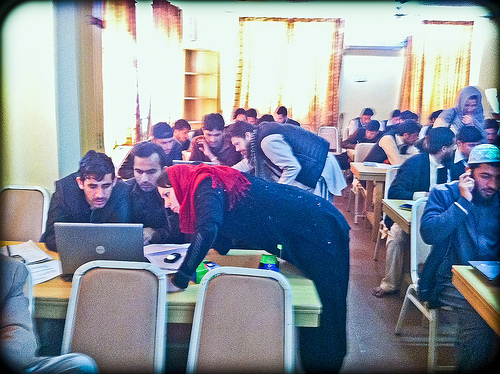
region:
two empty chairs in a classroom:
[56, 255, 298, 372]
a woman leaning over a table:
[146, 160, 358, 372]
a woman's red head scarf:
[162, 161, 252, 236]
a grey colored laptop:
[53, 217, 149, 279]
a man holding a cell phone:
[418, 144, 499, 371]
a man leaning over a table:
[221, 117, 348, 209]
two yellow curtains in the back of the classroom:
[233, 16, 473, 146]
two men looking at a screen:
[42, 137, 185, 248]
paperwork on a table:
[0, 235, 65, 286]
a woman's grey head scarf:
[455, 86, 487, 132]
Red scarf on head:
[158, 163, 239, 221]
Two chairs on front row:
[59, 262, 287, 372]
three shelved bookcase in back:
[173, 45, 233, 119]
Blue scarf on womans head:
[437, 84, 490, 119]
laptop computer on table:
[45, 217, 160, 257]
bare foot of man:
[364, 270, 403, 299]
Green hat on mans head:
[468, 144, 498, 164]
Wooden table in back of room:
[348, 158, 389, 248]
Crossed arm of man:
[2, 253, 47, 373]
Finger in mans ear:
[452, 167, 482, 206]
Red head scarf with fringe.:
[154, 153, 251, 245]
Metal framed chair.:
[185, 258, 305, 372]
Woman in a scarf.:
[144, 153, 360, 373]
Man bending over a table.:
[219, 112, 361, 212]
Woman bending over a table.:
[139, 150, 371, 372]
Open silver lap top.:
[41, 210, 161, 290]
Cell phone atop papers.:
[162, 243, 184, 271]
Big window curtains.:
[232, 12, 349, 127]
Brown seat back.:
[204, 270, 286, 372]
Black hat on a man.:
[153, 120, 174, 147]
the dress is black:
[173, 175, 357, 372]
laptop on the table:
[26, 213, 210, 294]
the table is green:
[269, 276, 326, 321]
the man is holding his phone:
[434, 150, 498, 250]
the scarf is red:
[145, 151, 255, 242]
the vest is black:
[245, 116, 355, 197]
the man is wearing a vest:
[256, 124, 367, 203]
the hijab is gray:
[450, 87, 491, 145]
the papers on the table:
[3, 240, 81, 312]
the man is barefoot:
[347, 125, 410, 314]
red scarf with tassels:
[164, 157, 261, 240]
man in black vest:
[227, 118, 353, 189]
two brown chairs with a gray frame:
[57, 244, 339, 372]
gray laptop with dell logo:
[45, 205, 159, 297]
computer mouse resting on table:
[153, 242, 195, 277]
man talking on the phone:
[405, 133, 498, 320]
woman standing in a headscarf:
[430, 77, 496, 134]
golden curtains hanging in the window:
[225, 12, 351, 140]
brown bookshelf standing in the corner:
[172, 33, 228, 144]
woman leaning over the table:
[152, 155, 371, 360]